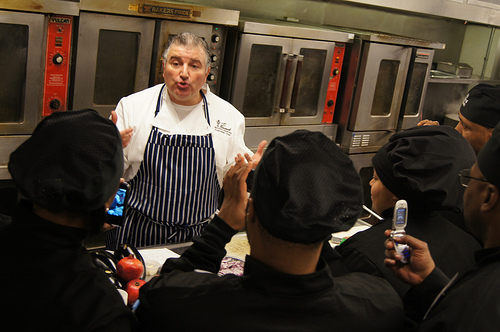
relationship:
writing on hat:
[458, 90, 474, 108] [462, 82, 499, 124]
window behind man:
[84, 19, 155, 128] [123, 14, 238, 139]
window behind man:
[93, 29, 142, 108] [118, 21, 238, 151]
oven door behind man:
[0, 10, 46, 136] [132, 22, 224, 150]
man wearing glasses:
[389, 123, 499, 328] [456, 163, 488, 188]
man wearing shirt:
[105, 29, 270, 253] [108, 82, 256, 193]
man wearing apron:
[105, 29, 270, 253] [114, 82, 224, 247]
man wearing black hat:
[124, 120, 418, 329] [237, 123, 366, 250]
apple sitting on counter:
[105, 248, 144, 280] [126, 224, 181, 259]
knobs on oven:
[325, 48, 339, 124] [226, 18, 365, 131]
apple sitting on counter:
[116, 253, 145, 281] [79, 217, 380, 311]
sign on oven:
[121, 0, 206, 21] [233, 15, 354, 137]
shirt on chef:
[114, 82, 244, 192] [90, 21, 252, 273]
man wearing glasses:
[141, 34, 224, 157] [443, 167, 495, 192]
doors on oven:
[230, 30, 340, 124] [222, 17, 344, 147]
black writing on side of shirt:
[214, 117, 233, 137] [108, 82, 256, 193]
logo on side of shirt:
[206, 117, 245, 139] [112, 99, 249, 244]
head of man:
[145, 16, 233, 108] [95, 24, 287, 242]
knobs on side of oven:
[326, 62, 340, 110] [220, 15, 354, 164]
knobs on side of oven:
[46, 96, 62, 111] [1, 1, 80, 181]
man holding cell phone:
[0, 108, 145, 332] [104, 180, 131, 227]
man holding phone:
[0, 108, 145, 332] [353, 187, 435, 247]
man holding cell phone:
[0, 108, 145, 332] [221, 150, 260, 193]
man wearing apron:
[105, 29, 270, 253] [100, 83, 222, 256]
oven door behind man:
[239, 37, 336, 127] [128, 22, 247, 231]